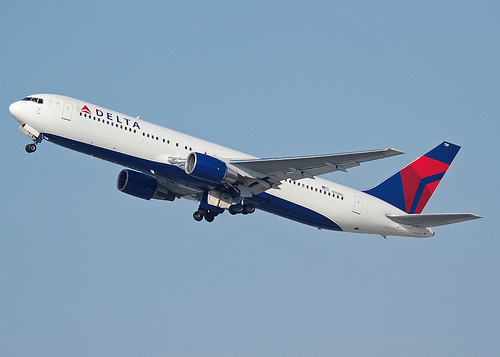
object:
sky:
[0, 0, 499, 356]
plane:
[7, 92, 483, 240]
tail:
[362, 137, 483, 240]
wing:
[227, 147, 406, 191]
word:
[96, 108, 141, 129]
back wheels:
[236, 203, 246, 213]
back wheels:
[192, 211, 203, 221]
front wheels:
[24, 143, 37, 153]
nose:
[7, 99, 28, 124]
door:
[61, 102, 73, 121]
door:
[352, 195, 363, 215]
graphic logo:
[81, 105, 92, 115]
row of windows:
[78, 109, 346, 201]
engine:
[182, 150, 247, 187]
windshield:
[21, 96, 43, 104]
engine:
[114, 167, 177, 202]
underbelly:
[38, 131, 344, 232]